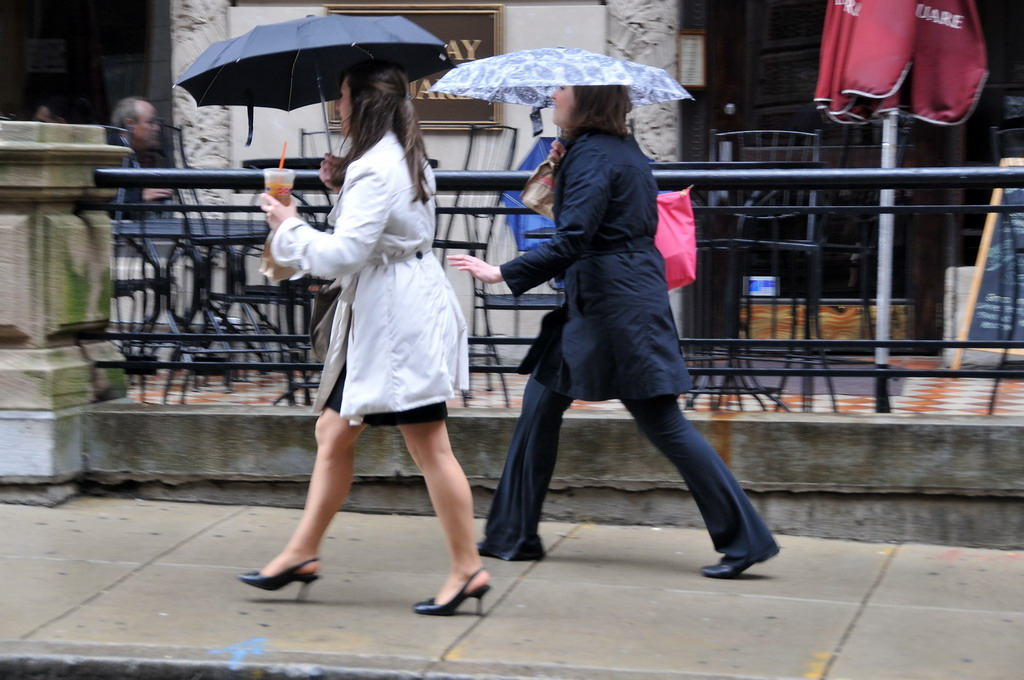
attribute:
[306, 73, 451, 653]
woman — YOUNG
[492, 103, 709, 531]
woman — YOUNG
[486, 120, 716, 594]
pant suit — BLUE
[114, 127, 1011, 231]
tables — DINING, OUTDOOR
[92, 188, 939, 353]
chairs — OUTDOOR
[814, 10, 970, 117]
parasol — FOLDED, RED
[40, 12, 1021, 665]
eatery — OUTDOOR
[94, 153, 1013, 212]
railing — METALLIC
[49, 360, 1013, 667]
sidewalk — EDGE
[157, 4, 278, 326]
pillar — CEMENT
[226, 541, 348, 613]
high heel — black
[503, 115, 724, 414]
jacket — dark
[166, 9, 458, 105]
umbrella — black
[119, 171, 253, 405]
safety rail — metal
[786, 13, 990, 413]
red umbrella — closed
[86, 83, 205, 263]
man — sitting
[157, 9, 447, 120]
umbrella — dark blue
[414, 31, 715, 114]
umbrella —  blue, white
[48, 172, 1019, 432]
tables — empty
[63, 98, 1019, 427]
chairs — empty